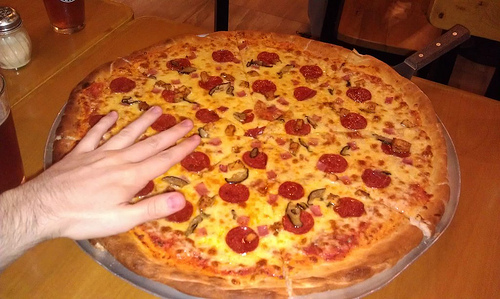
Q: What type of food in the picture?
A: Pizza.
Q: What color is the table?
A: Brown.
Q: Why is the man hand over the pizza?
A: Checking if hot.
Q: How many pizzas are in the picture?
A: One.